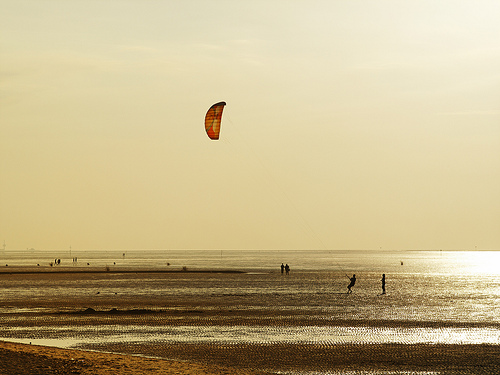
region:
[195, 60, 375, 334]
this is a large kite in the sky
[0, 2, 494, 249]
the sky is a yellowish color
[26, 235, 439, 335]
the water here is very shallow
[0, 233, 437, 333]
there are people in the water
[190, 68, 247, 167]
the kite is orange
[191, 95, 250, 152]
there is a design on the kite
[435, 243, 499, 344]
this is the reflection of the sun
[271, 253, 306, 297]
there are two people here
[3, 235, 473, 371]
people are at a large body of water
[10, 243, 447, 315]
people standing in the ocean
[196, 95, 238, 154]
kite flying in the sky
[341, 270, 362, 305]
person flying a kite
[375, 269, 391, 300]
person on the beach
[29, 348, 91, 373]
sand on the beach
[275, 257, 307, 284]
people on the beach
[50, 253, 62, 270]
people on the beach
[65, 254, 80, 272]
people on the beach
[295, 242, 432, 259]
line on the horizon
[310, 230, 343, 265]
string of the kite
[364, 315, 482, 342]
water near the sand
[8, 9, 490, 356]
Picture taken at the beach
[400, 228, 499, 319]
Sun shining on the water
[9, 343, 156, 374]
Sand covering the ground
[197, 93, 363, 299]
Person flying a kite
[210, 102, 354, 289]
The kite is connected to a string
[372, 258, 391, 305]
Person watching the kite being flown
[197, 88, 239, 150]
The kite is made up of many colors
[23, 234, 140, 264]
Several people in the ocean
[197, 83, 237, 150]
The kite is curved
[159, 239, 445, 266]
The water is calm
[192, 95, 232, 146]
kite in the sky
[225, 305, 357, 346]
waves on the water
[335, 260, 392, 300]
people in the ocean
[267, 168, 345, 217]
the sky is hazy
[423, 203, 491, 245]
the sky is yellow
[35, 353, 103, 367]
sand on the beach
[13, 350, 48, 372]
shadow on the sand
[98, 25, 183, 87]
few clouds in sky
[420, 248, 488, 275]
sun on the water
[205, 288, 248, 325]
the water is calm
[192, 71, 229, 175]
kite in the sky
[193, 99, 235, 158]
orange and yellow kite in the air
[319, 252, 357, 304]
person flying the kite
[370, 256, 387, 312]
person standing watching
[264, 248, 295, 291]
two people on the beach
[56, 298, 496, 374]
beach is full of sand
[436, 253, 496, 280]
reflection of sun on the water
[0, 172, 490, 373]
it is dusk time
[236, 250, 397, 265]
water is calm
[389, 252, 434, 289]
person standing in water